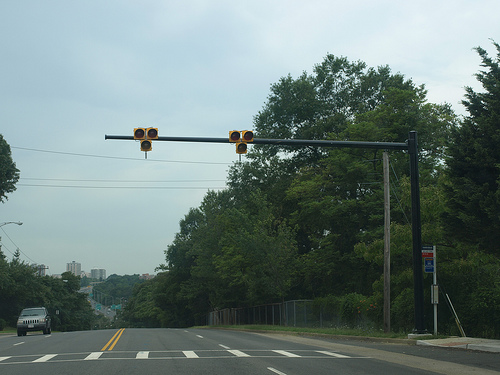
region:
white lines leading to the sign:
[383, 168, 440, 238]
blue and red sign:
[411, 234, 449, 277]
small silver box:
[419, 279, 452, 310]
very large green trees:
[296, 85, 413, 128]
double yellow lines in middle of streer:
[97, 323, 124, 365]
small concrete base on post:
[381, 317, 440, 346]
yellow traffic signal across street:
[217, 121, 269, 158]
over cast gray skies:
[86, 198, 152, 240]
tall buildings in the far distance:
[41, 248, 126, 288]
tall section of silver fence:
[211, 291, 350, 326]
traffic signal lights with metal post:
[125, 123, 263, 155]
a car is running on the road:
[16, 301, 66, 351]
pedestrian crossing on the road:
[37, 342, 318, 367]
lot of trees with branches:
[205, 195, 347, 288]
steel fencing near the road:
[221, 309, 333, 326]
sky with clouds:
[46, 165, 156, 258]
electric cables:
[49, 145, 234, 197]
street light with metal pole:
[2, 212, 29, 238]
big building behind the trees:
[66, 260, 128, 287]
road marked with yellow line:
[95, 315, 130, 347]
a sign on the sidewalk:
[418, 241, 443, 335]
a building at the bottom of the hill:
[62, 249, 113, 282]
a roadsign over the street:
[106, 299, 129, 314]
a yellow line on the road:
[102, 319, 125, 354]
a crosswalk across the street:
[6, 345, 363, 362]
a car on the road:
[9, 297, 51, 339]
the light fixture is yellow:
[130, 127, 162, 152]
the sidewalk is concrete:
[412, 329, 497, 356]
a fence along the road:
[207, 302, 421, 348]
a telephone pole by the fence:
[375, 152, 397, 338]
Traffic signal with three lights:
[128, 123, 255, 169]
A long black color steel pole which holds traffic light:
[104, 122, 439, 337]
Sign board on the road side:
[424, 243, 454, 345]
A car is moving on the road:
[16, 304, 56, 335]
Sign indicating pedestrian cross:
[92, 345, 359, 373]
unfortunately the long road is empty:
[57, 305, 407, 370]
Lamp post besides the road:
[6, 212, 37, 258]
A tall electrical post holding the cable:
[379, 147, 401, 339]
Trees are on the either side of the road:
[1, 46, 498, 328]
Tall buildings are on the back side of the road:
[64, 253, 115, 284]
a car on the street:
[8, 301, 57, 338]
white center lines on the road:
[178, 320, 300, 373]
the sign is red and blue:
[420, 244, 435, 257]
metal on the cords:
[436, 280, 476, 341]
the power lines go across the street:
[2, 133, 387, 201]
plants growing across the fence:
[308, 282, 438, 333]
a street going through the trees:
[74, 283, 122, 320]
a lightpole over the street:
[0, 215, 30, 237]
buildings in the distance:
[83, 264, 113, 286]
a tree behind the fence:
[429, 39, 498, 258]